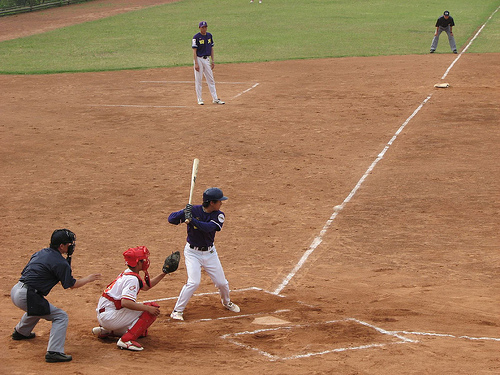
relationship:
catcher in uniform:
[10, 223, 104, 371] [9, 245, 81, 344]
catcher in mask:
[10, 223, 104, 371] [65, 230, 79, 266]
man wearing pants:
[180, 17, 251, 110] [192, 55, 220, 100]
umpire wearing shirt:
[424, 8, 465, 57] [434, 18, 459, 29]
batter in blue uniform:
[156, 154, 264, 330] [162, 203, 229, 248]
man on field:
[180, 17, 251, 110] [3, 7, 499, 374]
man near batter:
[180, 17, 251, 110] [156, 154, 264, 330]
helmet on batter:
[201, 185, 231, 204] [156, 154, 264, 330]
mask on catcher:
[65, 230, 79, 266] [10, 223, 104, 371]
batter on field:
[156, 154, 264, 330] [3, 7, 499, 374]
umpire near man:
[424, 8, 465, 57] [180, 17, 251, 110]